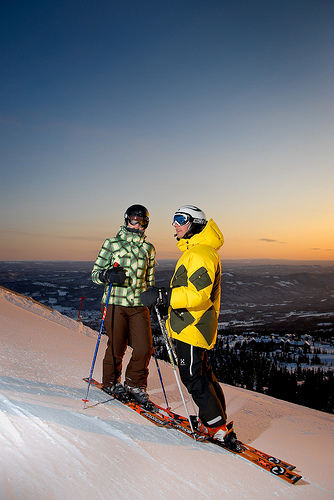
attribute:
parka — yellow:
[162, 212, 227, 350]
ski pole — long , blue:
[81, 266, 117, 407]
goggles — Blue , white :
[173, 215, 209, 226]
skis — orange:
[158, 403, 296, 471]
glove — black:
[100, 267, 132, 286]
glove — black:
[140, 284, 175, 303]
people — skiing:
[87, 196, 234, 443]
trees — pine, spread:
[233, 307, 325, 364]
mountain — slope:
[19, 295, 325, 498]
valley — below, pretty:
[91, 203, 331, 416]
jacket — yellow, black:
[165, 229, 226, 329]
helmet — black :
[124, 200, 157, 224]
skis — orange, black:
[150, 298, 196, 446]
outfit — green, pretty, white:
[100, 228, 150, 385]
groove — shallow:
[113, 417, 173, 484]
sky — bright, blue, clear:
[1, 0, 333, 260]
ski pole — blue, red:
[82, 262, 122, 408]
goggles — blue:
[169, 212, 192, 230]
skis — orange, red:
[82, 375, 301, 485]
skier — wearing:
[66, 164, 155, 392]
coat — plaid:
[95, 227, 157, 309]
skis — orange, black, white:
[54, 250, 213, 465]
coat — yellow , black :
[166, 217, 225, 349]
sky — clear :
[29, 26, 326, 192]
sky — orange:
[274, 213, 324, 239]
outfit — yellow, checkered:
[170, 224, 228, 422]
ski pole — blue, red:
[84, 263, 123, 403]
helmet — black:
[116, 198, 153, 224]